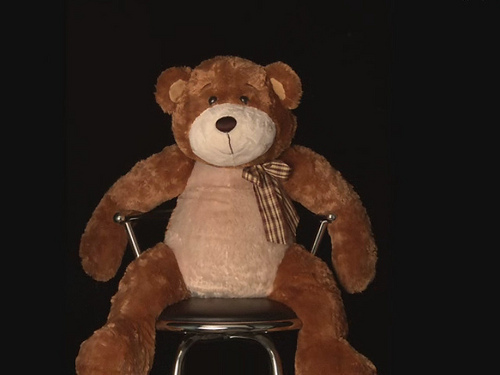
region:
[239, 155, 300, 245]
beige and brown ribbon on the bear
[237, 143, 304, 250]
bow on the bear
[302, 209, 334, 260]
metal arm of the chair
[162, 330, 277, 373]
metal legs of the chair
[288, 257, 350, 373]
leg hanging off the chair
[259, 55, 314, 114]
bent ear of the bear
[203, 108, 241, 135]
brown thread nose on the bear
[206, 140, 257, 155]
thread mouth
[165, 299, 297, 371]
metal chair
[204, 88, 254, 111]
black eyes on the bear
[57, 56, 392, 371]
Brown teddy bear sitting on a chair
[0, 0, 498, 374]
Black background behind the teddy bear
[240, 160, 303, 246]
Brown ribbon on the neck of the teddy bear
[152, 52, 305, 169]
Teddy bear's face smiling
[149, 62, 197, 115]
Right ear of the teddy bear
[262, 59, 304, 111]
left ear of the teddy bear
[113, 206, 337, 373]
Black and silver chair with teddy bear on the chair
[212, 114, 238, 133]
Dark brown nose of the teddy bear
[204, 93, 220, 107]
Right eye of the teddy bear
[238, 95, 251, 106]
left eye of the teddy bear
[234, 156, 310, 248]
beige and brown bow on the bear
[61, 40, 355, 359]
bear on the chair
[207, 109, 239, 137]
brown nose on the bear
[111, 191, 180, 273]
metal arm on the chair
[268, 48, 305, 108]
ear bent forward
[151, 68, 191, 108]
ear on the bear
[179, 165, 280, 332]
beige belly on the bear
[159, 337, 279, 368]
metal legs on the chair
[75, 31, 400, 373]
a brown teddy bear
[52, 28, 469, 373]
the bear is sitting on a black chair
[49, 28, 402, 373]
the chair is silver with a black leather seat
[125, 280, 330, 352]
the seat is leather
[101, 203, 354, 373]
the legs and arm rest are metal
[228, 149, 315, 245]
a brown plaid ribbon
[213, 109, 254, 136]
a brown nose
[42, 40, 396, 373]
the bear has a brown nose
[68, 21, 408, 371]
the bear has black eyes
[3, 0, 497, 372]
a dark black background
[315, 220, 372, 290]
paw of the bear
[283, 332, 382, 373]
paw of the bear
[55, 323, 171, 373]
paw of the bear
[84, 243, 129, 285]
paw of the bear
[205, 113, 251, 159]
nose of the bear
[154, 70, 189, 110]
ear of the bear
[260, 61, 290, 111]
ear of the bear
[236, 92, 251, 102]
eye of the bear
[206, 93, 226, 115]
eye of the bear